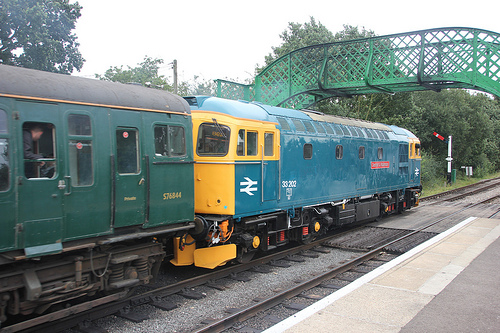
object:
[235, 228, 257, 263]
wheel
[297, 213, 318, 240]
wheel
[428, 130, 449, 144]
sign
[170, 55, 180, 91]
utility pole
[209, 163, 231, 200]
paint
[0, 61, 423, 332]
car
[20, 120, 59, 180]
window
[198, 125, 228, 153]
window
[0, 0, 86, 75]
tree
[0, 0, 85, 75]
leaves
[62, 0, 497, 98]
bright sky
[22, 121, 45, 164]
man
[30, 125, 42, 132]
hat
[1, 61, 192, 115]
roof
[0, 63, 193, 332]
front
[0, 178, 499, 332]
railroad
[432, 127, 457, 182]
switch signal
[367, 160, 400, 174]
lettering label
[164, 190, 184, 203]
writting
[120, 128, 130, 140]
sticker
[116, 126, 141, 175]
window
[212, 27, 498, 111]
bridge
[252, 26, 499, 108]
fence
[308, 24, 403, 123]
green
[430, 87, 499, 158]
tree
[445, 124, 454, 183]
pole